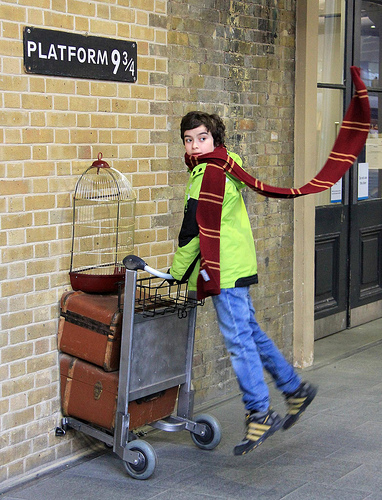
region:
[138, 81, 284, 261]
kid looking backwards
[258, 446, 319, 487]
ground below the kid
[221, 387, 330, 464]
shoes on the kid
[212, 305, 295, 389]
blue jeans on the kid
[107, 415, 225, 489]
wheels on the object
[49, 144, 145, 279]
cage next to the kid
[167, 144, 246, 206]
scarf around kid's neck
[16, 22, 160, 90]
writing on a sign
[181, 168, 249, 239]
green and black jacket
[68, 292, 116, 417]
suitcases on the rack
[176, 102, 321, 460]
the boy in jumping in air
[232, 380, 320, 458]
the boy's shoes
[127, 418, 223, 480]
the wheels on the cart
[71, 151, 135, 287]
the bird cage on the cart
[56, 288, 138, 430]
the luggages on the cart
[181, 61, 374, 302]
the long red scarf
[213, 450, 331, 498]
the gray sidewalk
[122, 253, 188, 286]
the handle on the cart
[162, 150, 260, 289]
the boy's green jacket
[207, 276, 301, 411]
the boy's blue jeans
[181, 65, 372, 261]
A long burgandy scarf with yellow stripes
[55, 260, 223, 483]
A two wheeled luggage cart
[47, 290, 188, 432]
two pieces of brown luggage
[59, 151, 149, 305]
a silver and red bird cage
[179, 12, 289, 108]
a gray and brown brick wall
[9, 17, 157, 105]
a black train platform sign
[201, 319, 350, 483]
feet jumping off of the ground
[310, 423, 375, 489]
a gray asphalt sidewalk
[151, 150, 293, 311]
a yellow coat with black accents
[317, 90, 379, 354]
set of black double doors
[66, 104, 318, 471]
the boy entering the wall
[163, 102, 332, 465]
the boy is floating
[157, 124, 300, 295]
the boy wearing a scarf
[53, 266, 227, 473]
the luggage on the cart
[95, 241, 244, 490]
the cart is metal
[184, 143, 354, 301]
the scarf is maroon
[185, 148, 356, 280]
the scarf is striped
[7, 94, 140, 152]
the wall is brick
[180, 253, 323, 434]
the boy wearing blue jeans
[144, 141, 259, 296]
the boy wearing a neon green jacket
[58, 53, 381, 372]
a boy wearing a scarf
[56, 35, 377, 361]
a boy flying in the air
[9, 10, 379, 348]
a boy going into platform 9 3/4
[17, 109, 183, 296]
a bird cage going into wall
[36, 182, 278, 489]
suitcases going into wall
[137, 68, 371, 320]
a boy wearing a green jacket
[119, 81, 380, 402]
a boy wearing a jacket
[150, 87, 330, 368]
a boy wearing jeans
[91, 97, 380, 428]
a boy wearing blue jeans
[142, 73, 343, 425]
a boy wearing shoes